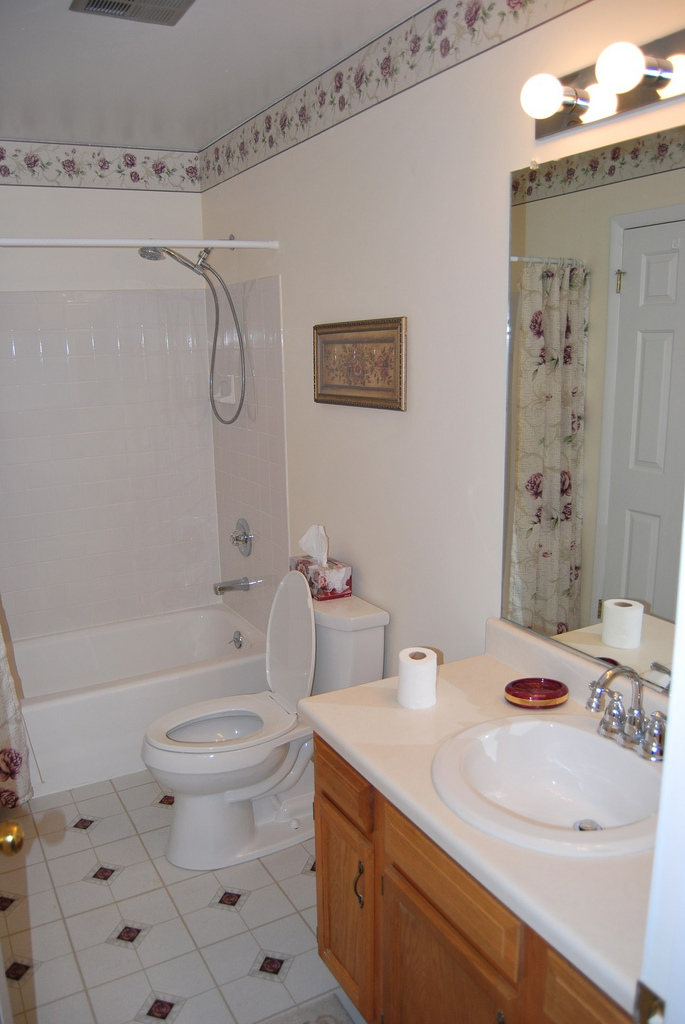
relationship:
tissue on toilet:
[299, 521, 350, 578] [134, 586, 365, 818]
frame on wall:
[300, 304, 414, 423] [278, 159, 474, 512]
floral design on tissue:
[307, 573, 351, 602] [290, 521, 350, 598]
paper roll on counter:
[393, 644, 440, 712] [288, 670, 499, 752]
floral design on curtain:
[517, 304, 584, 366] [509, 254, 611, 630]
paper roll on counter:
[393, 645, 440, 712] [298, 652, 661, 1014]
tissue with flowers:
[290, 521, 350, 598] [292, 560, 353, 601]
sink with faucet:
[432, 712, 663, 856] [585, 663, 647, 750]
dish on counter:
[500, 675, 570, 709] [298, 652, 661, 1014]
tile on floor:
[64, 888, 199, 991] [0, 769, 377, 1021]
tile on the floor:
[210, 913, 330, 1008] [43, 804, 158, 1021]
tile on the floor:
[210, 913, 330, 1008] [9, 864, 102, 1019]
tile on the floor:
[293, 957, 322, 994] [23, 863, 93, 1021]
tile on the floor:
[279, 960, 307, 983] [25, 868, 104, 1022]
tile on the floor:
[210, 913, 330, 1008] [54, 854, 146, 995]